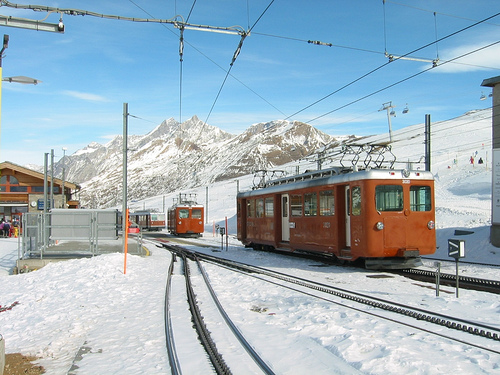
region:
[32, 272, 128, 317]
white snow on ground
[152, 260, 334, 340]
several train tracks in the ground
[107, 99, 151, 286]
large silver pole on the side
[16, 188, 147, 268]
clear chain link enclosure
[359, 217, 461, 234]
lights on front of train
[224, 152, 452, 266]
large brown train ontrack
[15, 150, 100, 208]
slanted roof on building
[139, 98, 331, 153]
snow covered mountain range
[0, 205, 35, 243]
people standing by station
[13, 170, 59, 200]
clear windows in building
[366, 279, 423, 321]
edge of a rail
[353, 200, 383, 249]
edge of a train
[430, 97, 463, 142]
part of a wire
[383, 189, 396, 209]
part of a window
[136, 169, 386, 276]
Train on the tracks.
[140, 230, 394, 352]
Tracks with trains on it.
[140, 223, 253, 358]
Snow on the ground.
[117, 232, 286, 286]
Rails in the snow.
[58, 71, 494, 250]
Mountain in the background.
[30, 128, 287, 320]
Poles on the side.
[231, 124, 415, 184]
Wires connecting the tram.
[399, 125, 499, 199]
Snow on the hill.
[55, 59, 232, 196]
Blue sky with clouds.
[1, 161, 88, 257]
Cabin on the snow.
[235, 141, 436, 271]
an electric train car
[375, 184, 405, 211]
the front windshield on the train car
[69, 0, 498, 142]
an electric train grid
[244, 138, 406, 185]
electric wire contact stand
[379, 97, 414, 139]
ski lift tower in the distance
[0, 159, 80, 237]
a train station building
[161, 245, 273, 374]
train tracks in the snow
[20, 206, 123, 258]
fenced in power transformer security area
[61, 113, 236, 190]
tall mountains in the distance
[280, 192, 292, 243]
the side door train car entrance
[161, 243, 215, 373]
that is a train track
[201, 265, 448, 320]
that is a train track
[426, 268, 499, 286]
that is a train track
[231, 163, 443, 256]
that is a train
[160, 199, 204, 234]
that is a train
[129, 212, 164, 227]
that is a train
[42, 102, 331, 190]
hills on the background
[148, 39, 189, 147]
that is a wire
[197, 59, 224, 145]
that is a wire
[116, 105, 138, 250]
that is a pole